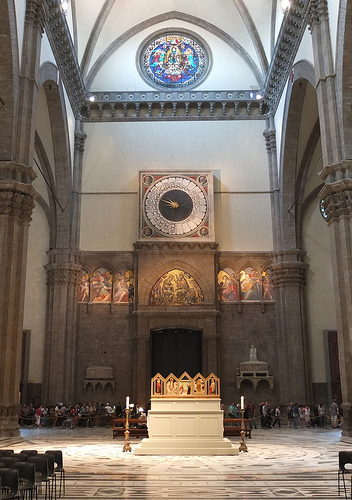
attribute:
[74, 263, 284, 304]
paintings — classical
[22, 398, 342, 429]
people — sitting, many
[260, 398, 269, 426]
person — standing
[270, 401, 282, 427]
person — standing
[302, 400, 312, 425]
person — standing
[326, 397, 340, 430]
person — standing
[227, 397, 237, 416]
person — standing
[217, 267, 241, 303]
art — classic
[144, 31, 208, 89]
window — stained, glass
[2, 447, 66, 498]
chairs — black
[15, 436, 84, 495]
chairs — empty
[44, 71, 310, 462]
building — gothic style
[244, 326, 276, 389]
statue — white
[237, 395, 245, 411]
candle — large, white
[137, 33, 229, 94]
window — circular, stained glass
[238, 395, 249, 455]
stand — candle stand, golden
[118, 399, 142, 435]
stand — metal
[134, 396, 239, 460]
pedestal — white, large